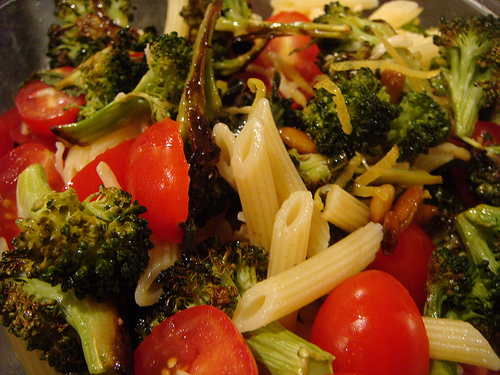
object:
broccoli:
[13, 162, 148, 295]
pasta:
[229, 122, 271, 247]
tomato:
[126, 119, 185, 241]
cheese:
[349, 153, 399, 200]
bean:
[391, 181, 423, 221]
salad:
[26, 27, 443, 318]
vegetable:
[271, 23, 371, 105]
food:
[116, 79, 330, 250]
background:
[6, 5, 55, 59]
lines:
[255, 159, 278, 240]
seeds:
[161, 356, 183, 369]